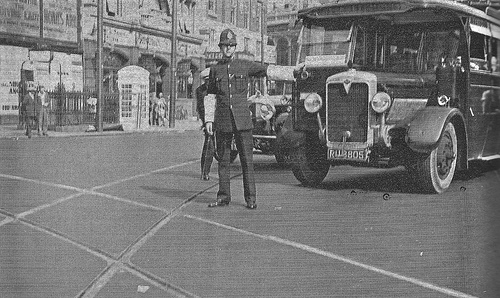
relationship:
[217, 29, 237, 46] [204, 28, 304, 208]
hat of man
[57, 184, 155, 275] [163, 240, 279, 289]
lines of road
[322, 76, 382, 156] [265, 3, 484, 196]
grill of bus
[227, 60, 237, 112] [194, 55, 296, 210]
buttons of uniform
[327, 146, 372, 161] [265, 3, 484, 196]
license plate on bus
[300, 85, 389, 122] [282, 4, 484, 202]
lights on bus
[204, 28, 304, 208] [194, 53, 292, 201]
man wearing uniform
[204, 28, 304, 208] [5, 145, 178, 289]
man standing street